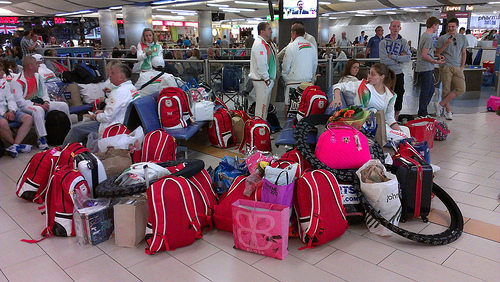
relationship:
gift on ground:
[229, 192, 293, 264] [190, 249, 303, 279]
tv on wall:
[276, 0, 324, 23] [276, 0, 325, 65]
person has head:
[439, 15, 471, 127] [445, 17, 461, 36]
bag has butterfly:
[229, 192, 293, 264] [232, 208, 278, 254]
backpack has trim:
[144, 177, 209, 257] [166, 173, 205, 231]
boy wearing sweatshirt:
[376, 18, 410, 101] [378, 33, 411, 74]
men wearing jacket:
[252, 16, 318, 98] [279, 39, 323, 86]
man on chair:
[98, 57, 141, 128] [117, 73, 211, 140]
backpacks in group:
[18, 140, 99, 242] [16, 143, 111, 240]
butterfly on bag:
[232, 208, 278, 254] [229, 192, 293, 264]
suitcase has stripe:
[386, 148, 436, 221] [397, 153, 426, 219]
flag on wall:
[0, 23, 21, 34] [2, 12, 99, 49]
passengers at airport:
[57, 19, 464, 225] [167, 1, 493, 271]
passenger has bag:
[128, 23, 172, 78] [131, 56, 157, 78]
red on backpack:
[168, 201, 189, 241] [144, 177, 209, 257]